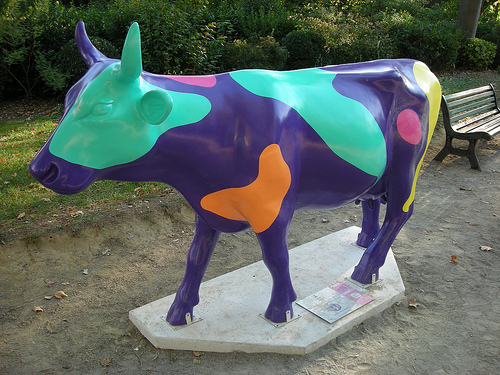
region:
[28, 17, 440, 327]
this is a statue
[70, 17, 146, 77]
these are his ears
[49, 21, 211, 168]
his partial face is green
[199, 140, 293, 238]
this color is orange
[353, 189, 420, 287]
these are his legs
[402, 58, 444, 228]
this color is yellow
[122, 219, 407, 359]
this is a brick platform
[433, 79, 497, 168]
this is a bench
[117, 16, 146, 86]
teal colored ceramic cow statue horn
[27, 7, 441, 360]
colorful cow statue on white base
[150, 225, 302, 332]
two purple cow statue legs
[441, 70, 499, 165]
one wood and metal park bench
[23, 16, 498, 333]
large statue next to bench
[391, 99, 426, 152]
large pink circle on back of cow statue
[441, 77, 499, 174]
sunlit wooden bench slats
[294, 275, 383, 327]
red and white plaque at statue base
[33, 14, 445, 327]
a colorful statue cow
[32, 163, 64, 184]
nostril of the cow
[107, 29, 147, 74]
a green horn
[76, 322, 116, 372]
the dirt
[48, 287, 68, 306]
a leaf on the ground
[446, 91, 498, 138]
the bench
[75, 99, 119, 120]
eye of the cow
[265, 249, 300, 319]
the cows front leg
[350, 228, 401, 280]
the cows back leg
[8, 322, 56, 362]
Small imprints in the dirt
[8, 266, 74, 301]
Small imprints in the dirt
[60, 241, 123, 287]
Small imprints in the dirt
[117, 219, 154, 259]
Small imprints in the dirt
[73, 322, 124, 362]
Small imprints in the dirt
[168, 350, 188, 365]
Small imprints in the dirt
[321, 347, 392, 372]
Small imprints in the dirt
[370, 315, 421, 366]
Small imprints in the dirt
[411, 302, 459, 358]
Small imprints in the dirt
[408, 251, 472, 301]
Small imprints in the dirt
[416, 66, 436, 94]
yellow paint on cow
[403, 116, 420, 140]
pink paint on cow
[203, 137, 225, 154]
purple paint on cow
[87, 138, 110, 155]
green paint on face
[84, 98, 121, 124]
right eye on cow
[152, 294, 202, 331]
left foot on cow